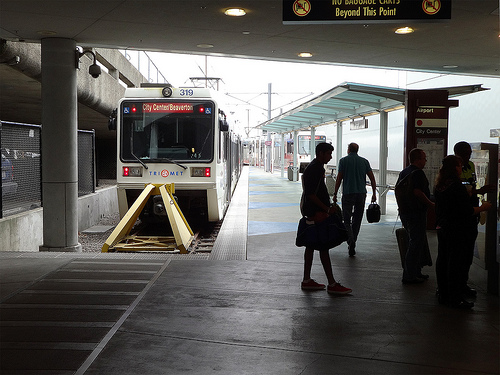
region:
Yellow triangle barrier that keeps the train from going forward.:
[98, 183, 195, 253]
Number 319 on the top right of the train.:
[177, 87, 193, 97]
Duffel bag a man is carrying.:
[292, 211, 353, 250]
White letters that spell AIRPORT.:
[415, 104, 435, 115]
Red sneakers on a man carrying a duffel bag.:
[300, 279, 353, 299]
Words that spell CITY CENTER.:
[414, 128, 443, 136]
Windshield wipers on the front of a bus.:
[125, 119, 187, 171]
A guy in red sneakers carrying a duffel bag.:
[296, 141, 353, 299]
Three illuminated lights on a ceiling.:
[222, 6, 414, 61]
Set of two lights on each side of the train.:
[122, 166, 210, 178]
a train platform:
[226, 75, 406, 206]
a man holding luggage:
[275, 137, 349, 313]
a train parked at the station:
[99, 64, 246, 247]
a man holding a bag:
[333, 141, 388, 241]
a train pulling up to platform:
[257, 101, 334, 171]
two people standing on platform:
[413, 130, 496, 310]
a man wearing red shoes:
[288, 142, 356, 309]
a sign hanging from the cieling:
[236, 0, 454, 46]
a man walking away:
[321, 127, 385, 267]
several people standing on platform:
[223, 97, 487, 310]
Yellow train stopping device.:
[101, 183, 197, 254]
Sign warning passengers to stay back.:
[283, 1, 453, 23]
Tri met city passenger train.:
[118, 85, 222, 223]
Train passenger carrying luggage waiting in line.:
[298, 141, 353, 296]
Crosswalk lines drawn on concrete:
[3, 251, 174, 373]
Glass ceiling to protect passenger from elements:
[252, 79, 405, 128]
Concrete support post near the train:
[36, 71, 76, 251]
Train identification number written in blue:
[125, 86, 213, 96]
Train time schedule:
[412, 136, 447, 198]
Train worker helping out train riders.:
[441, 140, 477, 207]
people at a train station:
[286, 140, 495, 334]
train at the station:
[112, 74, 277, 269]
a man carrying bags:
[295, 133, 353, 323]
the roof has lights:
[165, 7, 287, 55]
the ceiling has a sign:
[264, 2, 453, 31]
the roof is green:
[257, 88, 394, 138]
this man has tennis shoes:
[296, 276, 367, 303]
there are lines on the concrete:
[28, 253, 183, 372]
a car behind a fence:
[0, 142, 33, 214]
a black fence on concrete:
[2, 112, 107, 239]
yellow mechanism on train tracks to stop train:
[96, 184, 208, 255]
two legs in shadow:
[276, 246, 364, 301]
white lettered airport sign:
[409, 101, 440, 121]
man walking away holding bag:
[335, 141, 384, 254]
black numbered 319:
[173, 83, 198, 102]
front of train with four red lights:
[108, 85, 222, 192]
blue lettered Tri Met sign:
[143, 163, 186, 182]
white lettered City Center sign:
[413, 127, 443, 136]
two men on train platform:
[243, 117, 394, 302]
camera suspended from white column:
[62, 38, 109, 254]